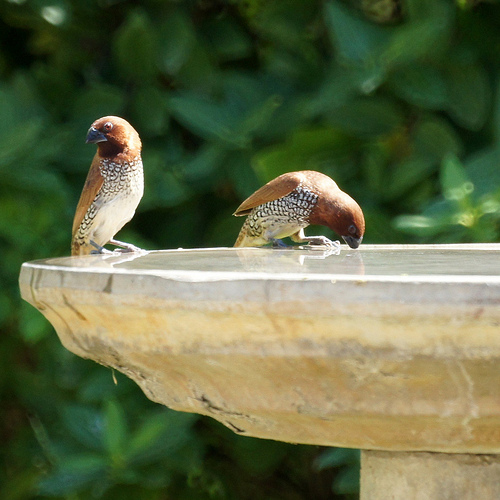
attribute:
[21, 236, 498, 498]
fountain — stone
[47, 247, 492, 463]
fountain — tan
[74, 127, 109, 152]
beak — black 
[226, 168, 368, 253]
bird — brown 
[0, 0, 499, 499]
plants — green 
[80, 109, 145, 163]
head — brown 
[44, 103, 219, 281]
bird — brown, white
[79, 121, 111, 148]
beak — small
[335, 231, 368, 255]
beak — small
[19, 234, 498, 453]
birdbath — stone 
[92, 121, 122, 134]
eye — open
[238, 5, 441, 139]
bushes — Green 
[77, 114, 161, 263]
brown bird — looking right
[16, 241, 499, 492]
water fountain — stone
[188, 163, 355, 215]
wing — brown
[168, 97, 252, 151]
leaf — green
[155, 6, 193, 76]
leaf — green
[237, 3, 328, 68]
leaf — green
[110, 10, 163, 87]
leaf — green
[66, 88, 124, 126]
leaf — green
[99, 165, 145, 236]
breast — white